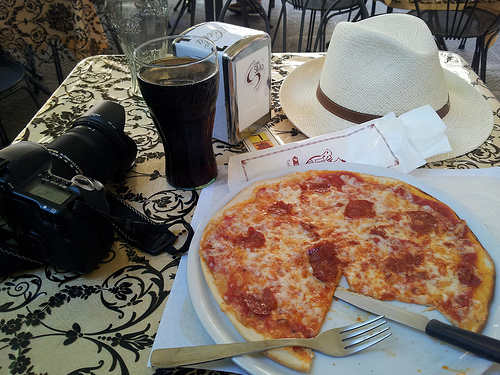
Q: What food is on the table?
A: Pizza.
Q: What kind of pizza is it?
A: Pepperoni.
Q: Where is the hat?
A: On the top right.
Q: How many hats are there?
A: 1.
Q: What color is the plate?
A: White.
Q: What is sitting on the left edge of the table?
A: Camera.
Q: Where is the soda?
A: In the glass.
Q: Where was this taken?
A: Restaurant.